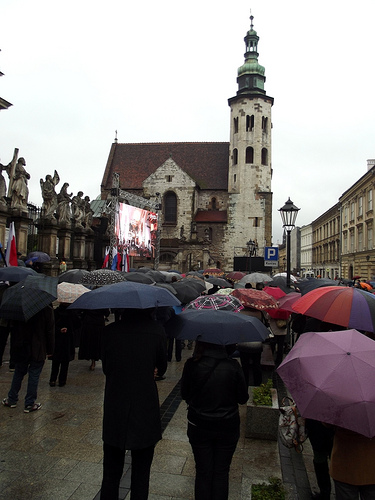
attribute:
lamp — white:
[278, 197, 301, 233]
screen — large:
[112, 185, 168, 265]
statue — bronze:
[8, 148, 32, 209]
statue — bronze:
[40, 171, 65, 217]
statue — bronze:
[57, 182, 73, 219]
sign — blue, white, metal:
[263, 246, 279, 267]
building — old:
[96, 7, 284, 271]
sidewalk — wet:
[4, 267, 317, 500]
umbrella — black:
[173, 307, 271, 355]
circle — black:
[343, 349, 355, 359]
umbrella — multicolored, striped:
[284, 283, 375, 329]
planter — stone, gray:
[246, 384, 280, 438]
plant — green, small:
[252, 379, 276, 408]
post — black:
[283, 231, 295, 290]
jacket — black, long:
[97, 320, 168, 449]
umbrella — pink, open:
[262, 287, 288, 320]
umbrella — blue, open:
[66, 281, 178, 312]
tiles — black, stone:
[147, 370, 188, 435]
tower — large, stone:
[222, 12, 276, 277]